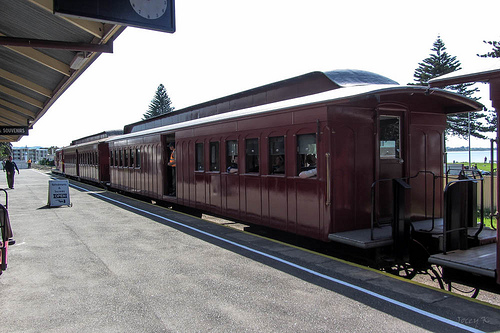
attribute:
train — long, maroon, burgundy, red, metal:
[51, 58, 498, 301]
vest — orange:
[167, 151, 176, 167]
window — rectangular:
[296, 131, 318, 178]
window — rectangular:
[266, 134, 288, 174]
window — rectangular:
[245, 141, 259, 175]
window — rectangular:
[225, 139, 237, 170]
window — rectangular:
[209, 142, 218, 172]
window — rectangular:
[193, 142, 205, 173]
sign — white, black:
[48, 177, 71, 209]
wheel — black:
[386, 253, 415, 279]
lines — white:
[36, 170, 489, 332]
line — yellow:
[51, 172, 500, 312]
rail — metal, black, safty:
[369, 171, 485, 240]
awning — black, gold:
[0, 2, 126, 142]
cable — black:
[397, 236, 482, 299]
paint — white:
[44, 173, 500, 332]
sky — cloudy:
[12, 0, 498, 148]